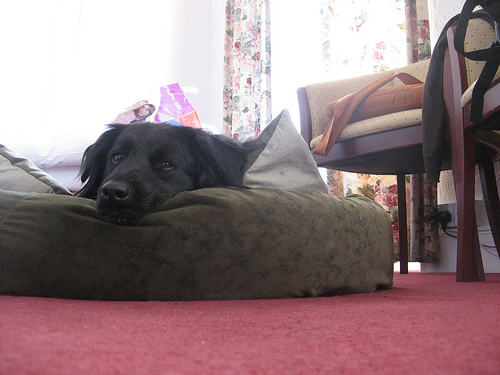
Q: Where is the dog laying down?
A: On a big pillow.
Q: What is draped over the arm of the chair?
A: A sweatshirt.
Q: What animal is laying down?
A: A black dog.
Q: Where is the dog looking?
A: At the camera.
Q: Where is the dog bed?
A: On the red carpet.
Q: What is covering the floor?
A: A red carpet.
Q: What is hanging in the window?
A: Flowered curtains.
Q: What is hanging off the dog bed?
A: The dog's nose.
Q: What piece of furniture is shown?
A: Aa armchair.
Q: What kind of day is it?
A: Bright and sunny.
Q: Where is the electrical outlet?
A: On the wall under the chair.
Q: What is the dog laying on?
A: A dog bed.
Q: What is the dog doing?
A: Laying on a dog bed.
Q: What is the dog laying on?
A: A dog bed.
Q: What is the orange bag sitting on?
A: A chair.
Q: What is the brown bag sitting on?
A: A chair.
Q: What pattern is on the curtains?
A: Flowers.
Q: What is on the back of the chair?
A: A black jacket.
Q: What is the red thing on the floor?
A: Carpet.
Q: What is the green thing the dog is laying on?
A: Dog bed.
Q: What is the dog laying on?
A: Dog bed.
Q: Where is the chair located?
A: In the room.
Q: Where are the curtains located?
A: By the window.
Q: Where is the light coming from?
A: The window.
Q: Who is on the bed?
A: A dog.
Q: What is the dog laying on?
A: A bed.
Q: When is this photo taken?
A: During the day.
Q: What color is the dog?
A: Black.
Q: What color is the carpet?
A: Red.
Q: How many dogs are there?
A: One.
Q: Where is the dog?
A: In the room.